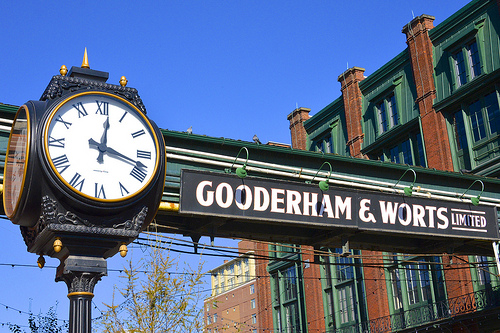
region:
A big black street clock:
[43, 93, 158, 205]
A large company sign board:
[181, 168, 498, 234]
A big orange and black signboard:
[7, 105, 47, 225]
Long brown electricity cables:
[301, 252, 425, 277]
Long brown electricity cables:
[162, 233, 271, 257]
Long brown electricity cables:
[111, 269, 373, 289]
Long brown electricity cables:
[11, 302, 66, 321]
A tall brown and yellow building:
[210, 265, 260, 327]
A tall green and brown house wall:
[347, 75, 456, 327]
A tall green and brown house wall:
[281, 110, 356, 330]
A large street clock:
[3, 47, 165, 330]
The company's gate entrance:
[0, 104, 497, 331]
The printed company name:
[182, 177, 498, 237]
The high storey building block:
[202, 0, 499, 332]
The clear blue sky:
[0, 0, 499, 331]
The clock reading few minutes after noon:
[45, 94, 165, 209]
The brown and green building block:
[203, 0, 498, 331]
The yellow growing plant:
[102, 222, 229, 332]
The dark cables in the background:
[0, 218, 499, 273]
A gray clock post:
[1, 52, 168, 332]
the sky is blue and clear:
[1, 1, 384, 46]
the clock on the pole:
[9, 58, 171, 287]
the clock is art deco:
[15, 44, 162, 260]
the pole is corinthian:
[32, 246, 117, 331]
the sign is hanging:
[185, 161, 496, 266]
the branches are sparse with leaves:
[128, 258, 215, 327]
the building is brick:
[258, 13, 478, 318]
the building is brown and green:
[269, 5, 491, 325]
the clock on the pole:
[7, 99, 39, 215]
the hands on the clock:
[82, 112, 142, 176]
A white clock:
[46, 94, 158, 201]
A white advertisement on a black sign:
[192, 168, 498, 247]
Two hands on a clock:
[86, 117, 146, 169]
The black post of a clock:
[46, 250, 115, 331]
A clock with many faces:
[0, 65, 174, 240]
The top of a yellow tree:
[102, 254, 216, 331]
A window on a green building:
[449, 40, 491, 92]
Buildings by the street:
[205, 5, 497, 332]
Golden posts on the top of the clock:
[53, 45, 133, 86]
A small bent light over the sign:
[228, 146, 257, 183]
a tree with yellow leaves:
[110, 255, 210, 331]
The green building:
[252, 5, 499, 330]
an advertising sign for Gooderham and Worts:
[182, 171, 497, 233]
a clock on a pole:
[10, 44, 168, 331]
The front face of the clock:
[45, 90, 160, 202]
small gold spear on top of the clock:
[78, 47, 90, 65]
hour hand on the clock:
[97, 119, 112, 162]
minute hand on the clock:
[88, 137, 146, 169]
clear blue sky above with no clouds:
[2, 2, 467, 302]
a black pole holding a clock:
[60, 263, 105, 330]